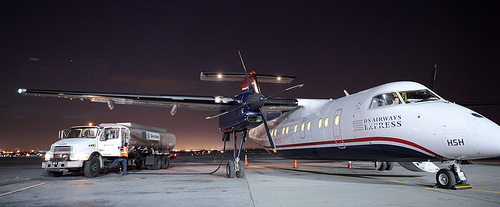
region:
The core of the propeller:
[248, 92, 269, 107]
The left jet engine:
[242, 90, 265, 123]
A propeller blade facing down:
[265, 120, 272, 144]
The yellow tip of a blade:
[271, 146, 277, 153]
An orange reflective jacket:
[121, 145, 128, 156]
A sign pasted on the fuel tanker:
[143, 130, 162, 138]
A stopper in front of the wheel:
[453, 184, 473, 189]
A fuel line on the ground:
[158, 170, 200, 174]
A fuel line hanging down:
[219, 154, 223, 166]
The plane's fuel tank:
[223, 118, 238, 125]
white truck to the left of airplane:
[40, 118, 177, 175]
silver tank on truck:
[107, 120, 173, 150]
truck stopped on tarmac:
[0, 152, 497, 202]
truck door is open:
[95, 121, 122, 151]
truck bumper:
[40, 156, 80, 162]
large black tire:
[80, 155, 100, 175]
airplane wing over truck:
[16, 85, 286, 110]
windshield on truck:
[65, 126, 95, 136]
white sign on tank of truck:
[143, 130, 162, 142]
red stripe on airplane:
[262, 135, 443, 164]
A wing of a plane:
[17, 84, 144, 104]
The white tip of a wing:
[16, 85, 27, 92]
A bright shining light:
[216, 73, 223, 78]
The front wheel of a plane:
[434, 168, 458, 189]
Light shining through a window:
[323, 116, 330, 128]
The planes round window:
[315, 116, 323, 128]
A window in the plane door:
[331, 106, 348, 150]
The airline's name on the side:
[364, 113, 401, 130]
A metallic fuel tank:
[128, 128, 177, 145]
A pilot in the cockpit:
[390, 95, 400, 104]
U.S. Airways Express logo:
[349, 111, 411, 136]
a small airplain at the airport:
[6, 31, 496, 193]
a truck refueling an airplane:
[42, 103, 246, 186]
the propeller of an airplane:
[195, 40, 310, 155]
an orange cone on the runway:
[242, 150, 254, 170]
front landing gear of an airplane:
[432, 158, 477, 195]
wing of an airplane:
[11, 70, 311, 135]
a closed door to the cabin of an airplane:
[325, 104, 354, 149]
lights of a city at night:
[175, 130, 221, 162]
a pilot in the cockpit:
[389, 89, 407, 110]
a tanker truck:
[25, 117, 187, 192]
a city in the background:
[1, 142, 264, 159]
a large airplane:
[15, 61, 498, 183]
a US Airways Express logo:
[339, 111, 419, 140]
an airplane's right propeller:
[216, 45, 301, 169]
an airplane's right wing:
[12, 80, 301, 142]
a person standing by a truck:
[112, 140, 130, 176]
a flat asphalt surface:
[7, 161, 479, 205]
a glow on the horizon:
[10, 134, 244, 149]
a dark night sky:
[20, 17, 490, 91]